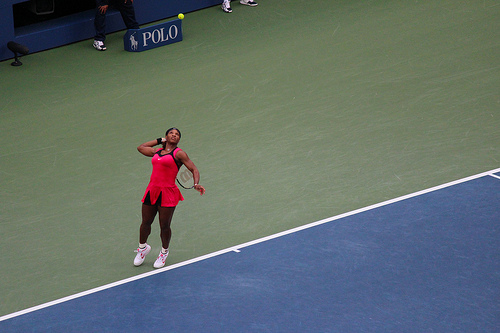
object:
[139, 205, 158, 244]
legs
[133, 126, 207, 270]
lady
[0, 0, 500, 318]
green court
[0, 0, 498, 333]
court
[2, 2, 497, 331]
ground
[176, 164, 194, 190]
racket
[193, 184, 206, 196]
hand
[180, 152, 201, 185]
arm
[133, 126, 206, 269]
tennis player